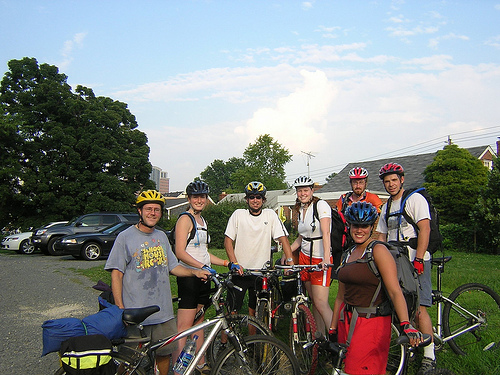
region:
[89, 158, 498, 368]
a group of bicyclists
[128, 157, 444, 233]
people wearing a helmet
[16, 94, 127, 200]
a lush green tree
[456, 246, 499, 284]
green grass on the lawn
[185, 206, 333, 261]
three people wearing white shirts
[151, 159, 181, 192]
the top of a building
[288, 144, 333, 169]
the top of a telephone pole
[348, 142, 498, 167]
the black roof of a house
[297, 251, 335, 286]
woman wearing red and white shorts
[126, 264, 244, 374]
a silvery bicycle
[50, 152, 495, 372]
people posing with their bicycles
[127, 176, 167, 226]
man wearing a yellow helmet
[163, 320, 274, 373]
water bottle attached to bicycle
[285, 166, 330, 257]
woman wearing a white shirt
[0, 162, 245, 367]
paved area to the left of bicyclists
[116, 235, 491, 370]
grassy area behind bicyclists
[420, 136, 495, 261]
green tree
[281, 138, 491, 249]
house beside tree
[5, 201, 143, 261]
vehicles parked beside each other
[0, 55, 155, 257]
large tree behind vehicles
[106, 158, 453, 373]
seven people standing around bikes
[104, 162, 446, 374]
seven people wearing helmets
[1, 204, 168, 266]
four parked cars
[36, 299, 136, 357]
blue bundle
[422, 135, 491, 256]
tall green tree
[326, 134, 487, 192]
gray roof of a building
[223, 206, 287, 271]
short sleeved white tee shirt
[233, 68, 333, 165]
puffy white cloud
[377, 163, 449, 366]
young man wearing a backpack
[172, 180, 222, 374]
young lady in a tank top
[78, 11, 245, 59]
Sky is blue color.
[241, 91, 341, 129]
Clouds are white color.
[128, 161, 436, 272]
People are wearing helmet.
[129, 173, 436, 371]
People are holding the bicycle.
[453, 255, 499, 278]
Grass is green color.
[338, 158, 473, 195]
Roof is grey color.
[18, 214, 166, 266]
Cars are parked behind the people.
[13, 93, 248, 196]
Trees are behind the people.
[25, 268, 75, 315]
Road is grey color.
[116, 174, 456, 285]
Seven people are standing with cycle.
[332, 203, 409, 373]
Woman wearing brown tank top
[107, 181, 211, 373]
Man wearing gray shirt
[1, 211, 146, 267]
Cars parked behind people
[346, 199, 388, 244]
Blue helmet on woman's head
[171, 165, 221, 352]
Woman wearing black helmet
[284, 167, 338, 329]
Women wearing white helmet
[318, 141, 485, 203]
Gray roof on house in background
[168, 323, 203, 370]
Water bottle on bike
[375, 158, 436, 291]
Man wearing red helmet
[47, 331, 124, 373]
Green and black bag on back of bike